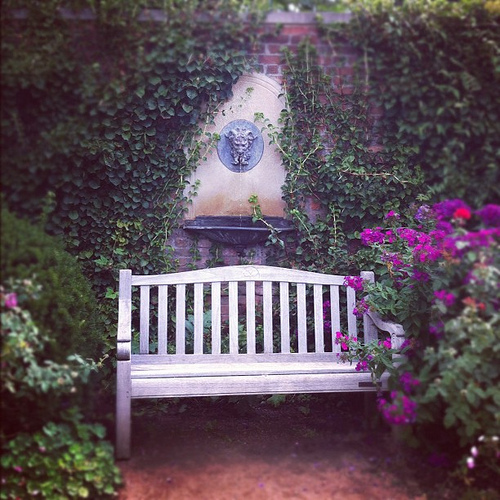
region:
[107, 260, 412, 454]
A wooden bench painted white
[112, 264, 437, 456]
A white bench in the park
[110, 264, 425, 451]
The white bench is made of wood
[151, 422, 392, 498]
Brown dirt beneath the park bench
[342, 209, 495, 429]
Blooming purple flowers by the bench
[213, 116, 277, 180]
A stone head behind the bench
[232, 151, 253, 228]
A small stream of water coming from the head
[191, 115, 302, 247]
A stone water fountain behind the bench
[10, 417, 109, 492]
A green bush on the ground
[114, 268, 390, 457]
the bench is made of wood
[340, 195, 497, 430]
the flowers are purple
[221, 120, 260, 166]
a fountain on the wall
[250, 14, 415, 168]
the wall is made of brick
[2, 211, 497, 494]
the greenery is leafy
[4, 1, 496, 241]
the wall has leaves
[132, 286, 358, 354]
the seat has bars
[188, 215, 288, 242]
the water lands in bowl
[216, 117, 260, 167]
the face has water coming from it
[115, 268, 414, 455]
a gray wooden bench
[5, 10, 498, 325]
a brick wall behind the bench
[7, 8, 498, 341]
green ivy on the brick wall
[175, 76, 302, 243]
a fountain on the brick wall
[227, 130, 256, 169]
a face spitting water out of wall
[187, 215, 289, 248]
a black iron basin of fountain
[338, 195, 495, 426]
purple flowers on the right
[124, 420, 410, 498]
dirt on ground in front of bench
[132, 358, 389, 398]
the seat of the bench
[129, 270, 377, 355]
the back of the bench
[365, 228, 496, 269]
purple flowers on leaves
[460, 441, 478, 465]
white and pink flowers on team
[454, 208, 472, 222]
pink flower in the bushes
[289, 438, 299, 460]
rocks on the ground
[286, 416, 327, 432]
small patch of green grass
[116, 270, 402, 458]
grey bench sitting outside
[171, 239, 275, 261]
brick wall on the background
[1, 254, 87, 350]
green bush on ground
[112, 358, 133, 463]
leg on the bench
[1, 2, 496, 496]
a botanical garden in a park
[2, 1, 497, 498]
a rest area in a botanical garden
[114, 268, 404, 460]
a wooden bench in a flower garden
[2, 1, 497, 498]
a flower garden in a park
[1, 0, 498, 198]
green plants on a brick wall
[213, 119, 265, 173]
a wall statute above a fountain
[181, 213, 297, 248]
a fountain bowl on the retaining wall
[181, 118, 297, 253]
a fountain and bowl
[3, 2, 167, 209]
green plants on the retaining wall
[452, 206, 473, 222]
a red flower on a plant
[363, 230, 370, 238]
A flower on a stem.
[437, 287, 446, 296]
A flower on a stem.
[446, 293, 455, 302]
A flower on a stem.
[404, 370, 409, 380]
A flower on a stem.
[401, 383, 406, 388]
A flower on a stem.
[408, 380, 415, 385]
A flower on a stem.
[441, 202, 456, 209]
A flower on a stem.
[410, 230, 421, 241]
A flower on a stem.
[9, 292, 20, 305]
A flower on a stem.